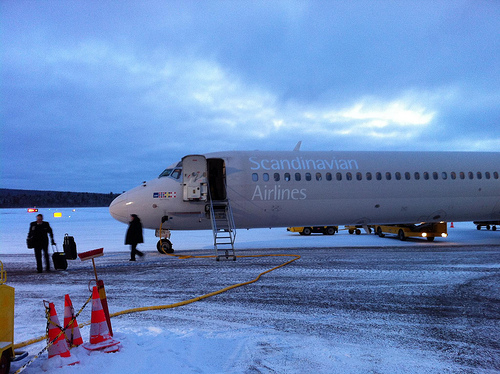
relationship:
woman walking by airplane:
[120, 211, 145, 273] [112, 164, 493, 265]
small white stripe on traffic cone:
[81, 320, 111, 342] [85, 284, 114, 374]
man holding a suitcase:
[25, 212, 56, 275] [53, 249, 63, 267]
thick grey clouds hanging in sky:
[2, 50, 497, 93] [17, 99, 494, 105]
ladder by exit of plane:
[206, 200, 237, 263] [113, 165, 496, 309]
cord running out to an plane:
[19, 227, 317, 367] [105, 149, 499, 264]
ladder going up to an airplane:
[206, 200, 237, 263] [104, 130, 494, 297]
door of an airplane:
[203, 156, 229, 203] [98, 154, 497, 254]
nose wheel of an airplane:
[154, 229, 174, 261] [117, 148, 497, 251]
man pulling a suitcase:
[17, 194, 72, 312] [50, 243, 64, 278]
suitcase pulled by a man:
[51, 247, 72, 277] [22, 205, 75, 334]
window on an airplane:
[302, 156, 312, 186] [100, 122, 494, 267]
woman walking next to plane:
[123, 211, 145, 261] [92, 128, 494, 275]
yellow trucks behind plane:
[283, 210, 489, 265] [113, 144, 498, 294]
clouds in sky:
[40, 52, 372, 136] [82, 118, 245, 166]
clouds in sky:
[0, 0, 499, 194] [17, 54, 434, 120]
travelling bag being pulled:
[26, 231, 70, 299] [53, 239, 63, 317]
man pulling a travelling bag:
[25, 212, 56, 275] [52, 245, 67, 279]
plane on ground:
[86, 122, 498, 291] [102, 306, 422, 374]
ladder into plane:
[206, 200, 245, 272] [101, 128, 498, 258]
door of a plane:
[212, 214, 228, 304] [103, 145, 497, 258]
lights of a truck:
[418, 229, 445, 238] [404, 216, 464, 273]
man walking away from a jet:
[25, 212, 56, 275] [104, 199, 495, 254]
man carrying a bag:
[25, 212, 56, 275] [57, 237, 83, 334]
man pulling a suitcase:
[25, 212, 56, 275] [49, 243, 70, 273]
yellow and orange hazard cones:
[29, 284, 119, 374] [34, 271, 118, 374]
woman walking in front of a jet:
[123, 211, 145, 261] [102, 143, 491, 263]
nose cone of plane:
[106, 193, 129, 222] [105, 149, 499, 264]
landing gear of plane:
[153, 229, 173, 255] [105, 149, 499, 264]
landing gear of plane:
[151, 229, 179, 258] [105, 149, 499, 264]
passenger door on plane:
[176, 150, 207, 203] [105, 149, 499, 264]